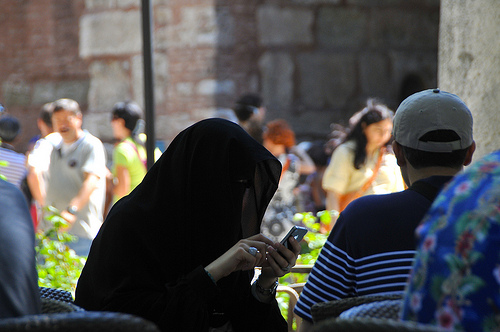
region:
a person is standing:
[33, 95, 100, 270]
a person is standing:
[110, 125, 305, 315]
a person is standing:
[303, 92, 487, 297]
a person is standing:
[331, 105, 409, 211]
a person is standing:
[251, 127, 306, 212]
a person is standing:
[228, 83, 264, 140]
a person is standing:
[23, 93, 63, 215]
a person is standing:
[100, 87, 162, 209]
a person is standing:
[0, 115, 28, 175]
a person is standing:
[2, 175, 34, 312]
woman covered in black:
[96, 112, 291, 316]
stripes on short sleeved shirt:
[289, 229, 412, 324]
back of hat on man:
[391, 89, 478, 162]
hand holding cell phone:
[266, 223, 308, 274]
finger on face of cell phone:
[244, 230, 281, 255]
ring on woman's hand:
[241, 242, 267, 262]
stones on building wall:
[271, 20, 400, 92]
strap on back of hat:
[417, 134, 462, 159]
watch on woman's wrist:
[256, 273, 285, 300]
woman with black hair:
[336, 97, 394, 174]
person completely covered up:
[132, 100, 293, 330]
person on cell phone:
[164, 97, 339, 325]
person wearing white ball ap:
[348, 65, 470, 329]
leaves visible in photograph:
[21, 172, 368, 297]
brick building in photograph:
[8, 12, 448, 160]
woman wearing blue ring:
[227, 231, 304, 291]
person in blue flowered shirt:
[411, 120, 498, 324]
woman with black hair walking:
[347, 105, 412, 215]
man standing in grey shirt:
[40, 87, 118, 259]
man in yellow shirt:
[88, 77, 169, 222]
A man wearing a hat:
[357, 99, 471, 213]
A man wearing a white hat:
[370, 70, 486, 210]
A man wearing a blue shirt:
[298, 50, 485, 320]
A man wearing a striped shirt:
[307, 92, 497, 324]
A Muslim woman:
[58, 108, 329, 328]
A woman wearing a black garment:
[96, 113, 291, 329]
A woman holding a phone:
[139, 125, 325, 316]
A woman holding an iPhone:
[130, 92, 320, 319]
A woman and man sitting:
[152, 74, 486, 319]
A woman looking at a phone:
[148, 100, 320, 309]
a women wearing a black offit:
[77, 78, 317, 326]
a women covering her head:
[98, 77, 328, 330]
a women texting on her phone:
[87, 85, 314, 320]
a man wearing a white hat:
[362, 56, 482, 187]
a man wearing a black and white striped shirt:
[294, 59, 482, 314]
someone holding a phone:
[208, 198, 319, 302]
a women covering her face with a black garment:
[68, 85, 333, 324]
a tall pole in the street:
[97, 2, 184, 197]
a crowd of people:
[22, 82, 463, 267]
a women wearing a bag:
[315, 81, 411, 203]